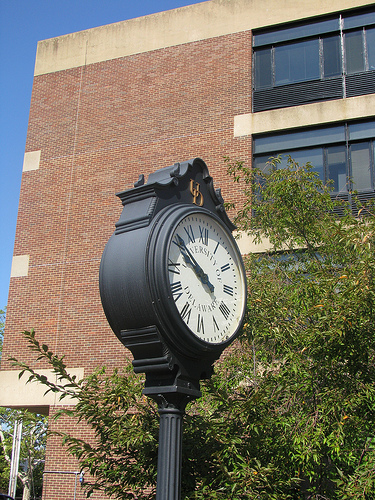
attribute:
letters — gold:
[189, 177, 212, 213]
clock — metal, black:
[164, 200, 253, 352]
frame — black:
[122, 159, 242, 398]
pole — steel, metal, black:
[156, 390, 179, 499]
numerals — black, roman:
[205, 222, 215, 258]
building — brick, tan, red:
[85, 69, 219, 156]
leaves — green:
[267, 181, 333, 248]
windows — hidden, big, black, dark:
[258, 29, 353, 117]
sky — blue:
[9, 4, 100, 29]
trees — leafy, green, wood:
[255, 214, 362, 482]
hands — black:
[176, 236, 218, 294]